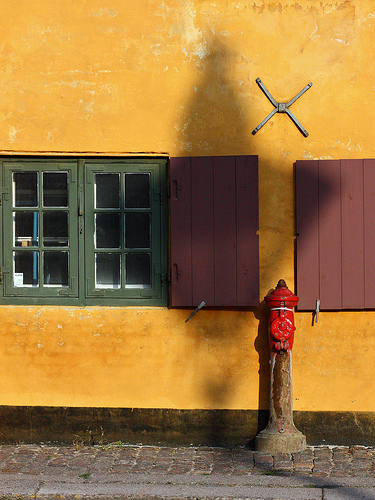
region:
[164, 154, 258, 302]
the shutter beside the window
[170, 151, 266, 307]
the shutter is purple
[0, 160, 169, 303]
the window is green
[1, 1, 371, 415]
the building is yellow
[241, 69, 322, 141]
the ''X'' on the building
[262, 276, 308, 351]
the hydrant beside the building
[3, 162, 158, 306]
the window is closed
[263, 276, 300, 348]
the hydrant is red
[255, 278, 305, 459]
hydrant on a post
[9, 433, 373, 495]
the sidewalk is cobblestone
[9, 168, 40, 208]
The window pane is rectangular.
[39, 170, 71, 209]
The window pane is rectangular.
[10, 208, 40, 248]
The window pane is rectangular.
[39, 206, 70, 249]
The window pane is rectangular.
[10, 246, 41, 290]
The window pane is rectangular.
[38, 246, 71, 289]
The window pane is rectangular.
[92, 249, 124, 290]
The window pane is rectangular.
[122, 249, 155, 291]
The window pane is rectangular.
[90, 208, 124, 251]
The window pane is rectangular.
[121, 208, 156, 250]
The window pane is rectangular.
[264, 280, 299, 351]
a red fire hydrant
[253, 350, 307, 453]
the rusted lower part of a fire hydrant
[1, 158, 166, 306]
two green framed windows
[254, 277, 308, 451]
a fire hydrant in front a building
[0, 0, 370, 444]
a gold building with two green framed windows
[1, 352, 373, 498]
a fire hydrant on the sidewalk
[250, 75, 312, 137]
metals on the exterior wall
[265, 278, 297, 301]
the top of a red hydrant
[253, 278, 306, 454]
a red fire hydrant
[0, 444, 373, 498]
a paved brick sidewalk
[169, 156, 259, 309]
a red maroon shutter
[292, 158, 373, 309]
a red maroon shutter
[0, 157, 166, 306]
a green framed window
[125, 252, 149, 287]
a divided window pane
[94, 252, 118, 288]
a divided window pane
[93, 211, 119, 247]
a divided window pane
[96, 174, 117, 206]
a divided window pane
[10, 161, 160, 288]
this is the window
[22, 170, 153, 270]
the window is closed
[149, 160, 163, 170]
this is the frame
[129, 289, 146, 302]
the frame is green in color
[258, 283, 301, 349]
the hydrant is red in color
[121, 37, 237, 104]
this is the wall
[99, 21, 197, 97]
the wall is yellow in color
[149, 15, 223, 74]
the wall is rusty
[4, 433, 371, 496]
a brick stone pavement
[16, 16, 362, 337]
a yellow building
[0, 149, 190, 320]
a green window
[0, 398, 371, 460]
a black trim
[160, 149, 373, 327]
a purple shutter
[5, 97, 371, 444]
a scene outside